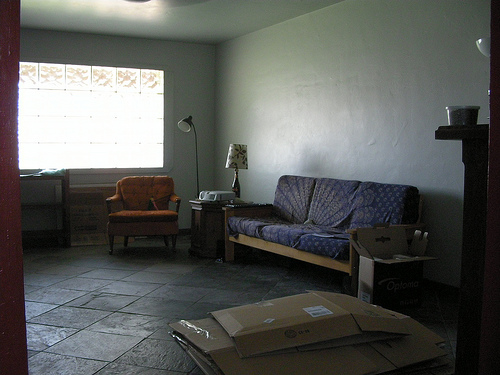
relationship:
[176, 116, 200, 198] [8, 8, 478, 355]
lamp in room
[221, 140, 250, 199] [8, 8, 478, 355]
lamp in room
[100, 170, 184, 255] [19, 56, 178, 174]
chair by window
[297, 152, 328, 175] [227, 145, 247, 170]
shade with pattern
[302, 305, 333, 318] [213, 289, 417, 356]
label on box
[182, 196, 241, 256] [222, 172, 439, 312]
table next to couch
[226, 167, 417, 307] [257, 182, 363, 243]
futon with cover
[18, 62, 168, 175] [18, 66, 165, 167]
window made of squares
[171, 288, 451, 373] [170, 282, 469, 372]
pile of boxes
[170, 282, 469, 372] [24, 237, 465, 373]
boxes on floor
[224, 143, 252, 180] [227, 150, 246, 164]
shade has leaves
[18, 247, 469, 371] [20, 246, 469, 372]
floor made of tiles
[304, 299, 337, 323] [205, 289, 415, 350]
label on box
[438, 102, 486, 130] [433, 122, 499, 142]
container sitting on mantle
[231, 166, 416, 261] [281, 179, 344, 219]
cushions with patterns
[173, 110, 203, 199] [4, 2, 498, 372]
lamp in corner of room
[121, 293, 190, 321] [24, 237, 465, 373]
tile on floor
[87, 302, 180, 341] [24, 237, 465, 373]
tile on floor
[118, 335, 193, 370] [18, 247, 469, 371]
tile on floor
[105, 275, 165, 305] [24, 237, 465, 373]
tile on floor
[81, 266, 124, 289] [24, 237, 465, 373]
tile on floor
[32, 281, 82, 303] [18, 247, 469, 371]
tile on floor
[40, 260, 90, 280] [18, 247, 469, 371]
tile on floor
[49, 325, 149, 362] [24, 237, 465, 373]
tile on floor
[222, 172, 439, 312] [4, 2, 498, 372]
couch in room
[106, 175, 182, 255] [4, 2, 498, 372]
chair in room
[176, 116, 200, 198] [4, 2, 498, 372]
lamp in room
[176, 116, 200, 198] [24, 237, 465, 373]
lamp on floor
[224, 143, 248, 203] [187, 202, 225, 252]
lamp on table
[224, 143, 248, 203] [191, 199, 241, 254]
lamp on table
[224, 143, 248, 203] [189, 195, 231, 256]
lamp on table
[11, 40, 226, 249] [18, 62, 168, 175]
wall with window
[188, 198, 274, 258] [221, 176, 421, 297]
table next to couch